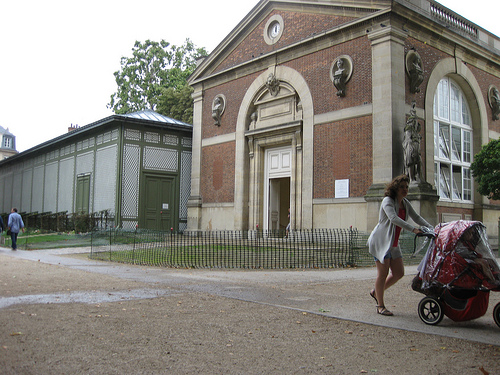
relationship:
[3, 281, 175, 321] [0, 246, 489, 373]
puddle on ground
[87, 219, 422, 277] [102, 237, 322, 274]
fence around grass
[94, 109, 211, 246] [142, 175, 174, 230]
building has door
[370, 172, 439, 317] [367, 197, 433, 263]
woman wearing sweater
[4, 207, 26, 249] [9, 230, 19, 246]
man wearing black pants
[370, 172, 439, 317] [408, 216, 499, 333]
woman pushing stroller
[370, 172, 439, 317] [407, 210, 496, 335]
woman pushing cart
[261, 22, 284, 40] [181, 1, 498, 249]
clock on building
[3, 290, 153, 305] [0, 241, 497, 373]
puddle in street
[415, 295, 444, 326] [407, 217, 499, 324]
wheel on a cart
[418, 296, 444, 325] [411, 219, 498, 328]
wheel on stroller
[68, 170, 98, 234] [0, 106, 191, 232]
door on building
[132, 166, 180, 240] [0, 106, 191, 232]
door on building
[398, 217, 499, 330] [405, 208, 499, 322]
stroller has a plastic cover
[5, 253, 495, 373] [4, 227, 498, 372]
rocks on ground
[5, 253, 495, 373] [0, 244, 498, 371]
rocks are next to sidewalk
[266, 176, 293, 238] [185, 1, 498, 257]
door open on buildng